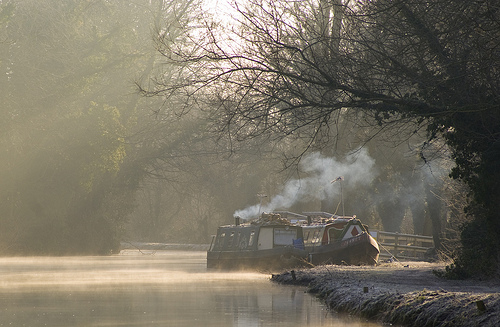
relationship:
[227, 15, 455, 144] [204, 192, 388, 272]
tree over boat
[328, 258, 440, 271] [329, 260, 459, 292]
light on ground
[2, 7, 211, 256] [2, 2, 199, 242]
tree has leaves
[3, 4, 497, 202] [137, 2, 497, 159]
sky seen through branches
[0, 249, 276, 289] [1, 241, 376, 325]
sun reflection on water